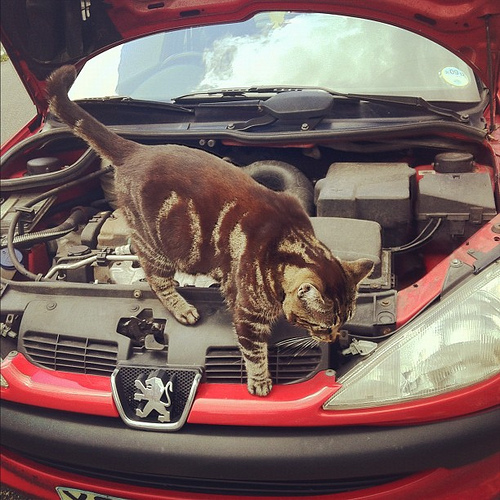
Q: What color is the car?
A: Red.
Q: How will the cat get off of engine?
A: He will jump.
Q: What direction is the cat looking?
A: Downward.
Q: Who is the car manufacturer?
A: PEUGEOT.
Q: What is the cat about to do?
A: Jump down.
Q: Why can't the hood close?
A: The cat is there.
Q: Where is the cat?
A: On top of engine.